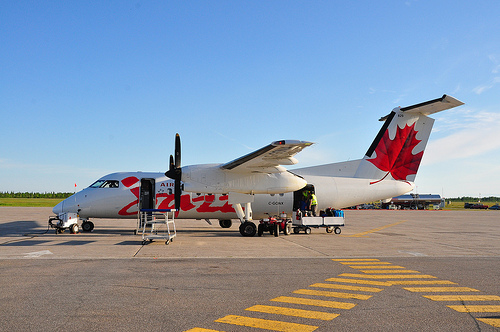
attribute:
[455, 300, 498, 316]
line — one, yellow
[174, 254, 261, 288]
pavement — some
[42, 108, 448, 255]
plane — red, white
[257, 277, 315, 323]
line — yellow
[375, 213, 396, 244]
line — yellow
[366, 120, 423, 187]
design — red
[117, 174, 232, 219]
design — red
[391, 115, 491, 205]
clouds — background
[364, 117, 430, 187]
maple leaf — red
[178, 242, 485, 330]
line — yellow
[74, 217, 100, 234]
tires — black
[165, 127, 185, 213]
propeller — black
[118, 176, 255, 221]
letters — red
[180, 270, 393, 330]
line — yellow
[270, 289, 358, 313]
line — yellow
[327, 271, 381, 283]
line — yellow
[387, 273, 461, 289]
line — yellow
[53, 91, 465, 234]
airplane — white, parked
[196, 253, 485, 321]
signs — yellow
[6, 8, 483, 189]
sky — blue, clear